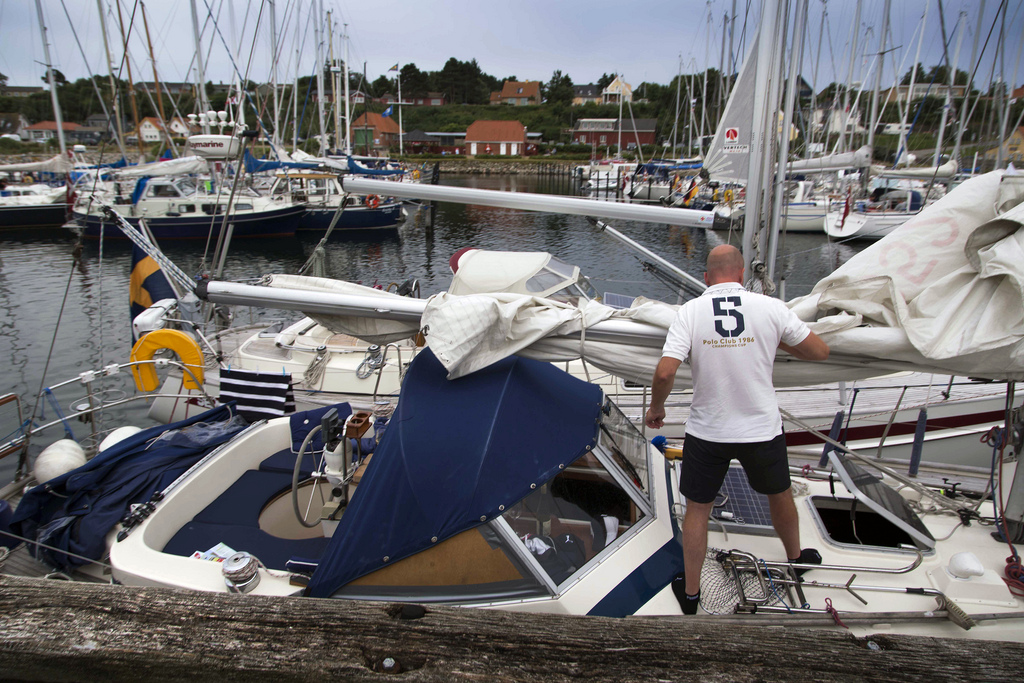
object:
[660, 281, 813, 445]
shirt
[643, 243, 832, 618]
man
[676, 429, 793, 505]
shorts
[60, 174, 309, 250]
boat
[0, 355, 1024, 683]
boat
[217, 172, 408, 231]
boat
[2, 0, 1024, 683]
dock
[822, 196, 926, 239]
boat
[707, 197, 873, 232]
boat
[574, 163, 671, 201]
boat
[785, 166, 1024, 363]
sail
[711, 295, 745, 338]
5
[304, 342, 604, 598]
cover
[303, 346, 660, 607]
windshield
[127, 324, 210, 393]
floaters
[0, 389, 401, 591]
interior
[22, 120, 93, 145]
buildings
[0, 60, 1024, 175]
shore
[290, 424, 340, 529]
steering wheel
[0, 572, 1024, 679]
wall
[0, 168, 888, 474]
water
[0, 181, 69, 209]
boat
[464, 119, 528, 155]
building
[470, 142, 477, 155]
window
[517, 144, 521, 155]
window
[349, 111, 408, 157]
building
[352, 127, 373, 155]
door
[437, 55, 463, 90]
trees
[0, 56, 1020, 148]
hill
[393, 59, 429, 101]
tree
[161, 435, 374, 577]
blue cushions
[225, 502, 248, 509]
seats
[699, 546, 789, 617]
fishing net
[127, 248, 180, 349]
blue flag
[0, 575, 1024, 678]
side